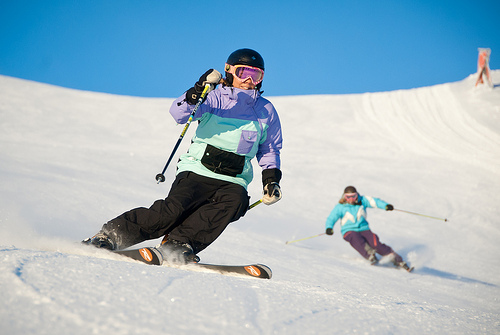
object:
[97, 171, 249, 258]
black pants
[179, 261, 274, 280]
skies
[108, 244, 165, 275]
skies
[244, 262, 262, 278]
logo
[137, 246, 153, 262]
logo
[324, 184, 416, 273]
girl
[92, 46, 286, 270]
female suit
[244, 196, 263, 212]
ski pole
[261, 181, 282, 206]
hand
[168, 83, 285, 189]
jacket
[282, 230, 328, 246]
ski pole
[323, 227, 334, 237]
hand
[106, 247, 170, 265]
ski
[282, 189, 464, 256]
ski poles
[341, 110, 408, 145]
landscape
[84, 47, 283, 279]
people skiing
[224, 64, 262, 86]
glasses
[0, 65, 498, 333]
mountain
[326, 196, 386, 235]
jacket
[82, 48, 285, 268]
female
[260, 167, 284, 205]
gloves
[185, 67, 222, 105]
gloves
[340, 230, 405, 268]
pants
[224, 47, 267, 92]
helmet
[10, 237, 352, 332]
tracks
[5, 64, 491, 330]
snow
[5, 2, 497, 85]
sky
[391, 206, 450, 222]
ski pole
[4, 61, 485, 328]
ski slope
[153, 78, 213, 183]
pole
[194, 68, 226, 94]
hand